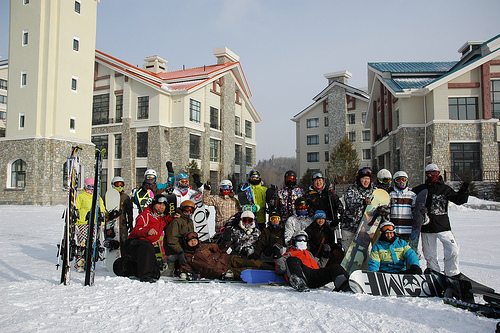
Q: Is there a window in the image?
A: Yes, there is a window.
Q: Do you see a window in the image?
A: Yes, there is a window.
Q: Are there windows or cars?
A: Yes, there is a window.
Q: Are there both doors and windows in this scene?
A: No, there is a window but no doors.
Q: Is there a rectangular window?
A: Yes, there is a rectangular window.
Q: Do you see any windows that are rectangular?
A: Yes, there is a window that is rectangular.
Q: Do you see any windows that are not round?
A: Yes, there is a rectangular window.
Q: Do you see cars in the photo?
A: No, there are no cars.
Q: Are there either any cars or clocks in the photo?
A: No, there are no cars or clocks.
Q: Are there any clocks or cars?
A: No, there are no cars or clocks.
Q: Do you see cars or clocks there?
A: No, there are no cars or clocks.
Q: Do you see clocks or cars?
A: No, there are no cars or clocks.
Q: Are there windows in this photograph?
A: Yes, there is a window.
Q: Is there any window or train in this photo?
A: Yes, there is a window.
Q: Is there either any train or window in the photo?
A: Yes, there is a window.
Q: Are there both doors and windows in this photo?
A: No, there is a window but no doors.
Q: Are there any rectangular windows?
A: Yes, there is a rectangular window.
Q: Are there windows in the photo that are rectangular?
A: Yes, there is a window that is rectangular.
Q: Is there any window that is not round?
A: Yes, there is a rectangular window.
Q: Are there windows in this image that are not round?
A: Yes, there is a rectangular window.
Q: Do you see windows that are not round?
A: Yes, there is a rectangular window.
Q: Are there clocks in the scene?
A: No, there are no clocks.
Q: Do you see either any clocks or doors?
A: No, there are no clocks or doors.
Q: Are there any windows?
A: Yes, there is a window.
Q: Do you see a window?
A: Yes, there is a window.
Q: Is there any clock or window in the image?
A: Yes, there is a window.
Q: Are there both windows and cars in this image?
A: No, there is a window but no cars.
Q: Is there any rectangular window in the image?
A: Yes, there is a rectangular window.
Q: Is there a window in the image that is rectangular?
A: Yes, there is a window that is rectangular.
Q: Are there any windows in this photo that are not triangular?
A: Yes, there is a rectangular window.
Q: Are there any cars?
A: No, there are no cars.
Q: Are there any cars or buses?
A: No, there are no cars or buses.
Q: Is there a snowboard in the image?
A: Yes, there is a snowboard.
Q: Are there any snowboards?
A: Yes, there is a snowboard.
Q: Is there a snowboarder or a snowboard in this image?
A: Yes, there is a snowboard.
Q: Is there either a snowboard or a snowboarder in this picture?
A: Yes, there is a snowboard.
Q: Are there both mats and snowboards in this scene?
A: No, there is a snowboard but no mats.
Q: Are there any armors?
A: No, there are no armors.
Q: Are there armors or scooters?
A: No, there are no armors or scooters.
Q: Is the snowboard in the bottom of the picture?
A: Yes, the snowboard is in the bottom of the image.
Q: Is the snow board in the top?
A: No, the snow board is in the bottom of the image.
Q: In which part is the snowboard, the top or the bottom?
A: The snowboard is in the bottom of the image.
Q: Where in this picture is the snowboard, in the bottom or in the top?
A: The snowboard is in the bottom of the image.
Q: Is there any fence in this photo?
A: No, there are no fences.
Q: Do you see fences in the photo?
A: No, there are no fences.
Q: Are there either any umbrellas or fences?
A: No, there are no fences or umbrellas.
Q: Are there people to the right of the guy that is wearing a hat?
A: Yes, there are people to the right of the guy.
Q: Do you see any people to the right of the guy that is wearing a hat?
A: Yes, there are people to the right of the guy.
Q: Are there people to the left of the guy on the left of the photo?
A: No, the people are to the right of the guy.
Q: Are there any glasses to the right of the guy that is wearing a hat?
A: No, there are people to the right of the guy.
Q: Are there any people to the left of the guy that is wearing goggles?
A: Yes, there are people to the left of the guy.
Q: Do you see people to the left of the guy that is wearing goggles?
A: Yes, there are people to the left of the guy.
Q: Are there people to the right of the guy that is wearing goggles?
A: No, the people are to the left of the guy.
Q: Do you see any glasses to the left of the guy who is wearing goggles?
A: No, there are people to the left of the guy.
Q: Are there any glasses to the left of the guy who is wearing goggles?
A: No, there are people to the left of the guy.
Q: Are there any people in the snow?
A: Yes, there is a person in the snow.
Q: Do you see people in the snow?
A: Yes, there is a person in the snow.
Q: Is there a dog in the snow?
A: No, there is a person in the snow.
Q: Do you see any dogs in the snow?
A: No, there is a person in the snow.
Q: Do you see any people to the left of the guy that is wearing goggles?
A: Yes, there is a person to the left of the guy.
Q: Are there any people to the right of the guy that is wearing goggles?
A: No, the person is to the left of the guy.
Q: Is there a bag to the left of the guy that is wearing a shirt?
A: No, there is a person to the left of the guy.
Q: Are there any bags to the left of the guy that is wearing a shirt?
A: No, there is a person to the left of the guy.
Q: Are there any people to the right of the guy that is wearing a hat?
A: Yes, there is a person to the right of the guy.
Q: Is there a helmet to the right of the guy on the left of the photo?
A: No, there is a person to the right of the guy.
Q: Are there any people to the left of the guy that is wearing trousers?
A: Yes, there is a person to the left of the guy.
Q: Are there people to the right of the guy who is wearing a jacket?
A: No, the person is to the left of the guy.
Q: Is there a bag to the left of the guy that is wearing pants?
A: No, there is a person to the left of the guy.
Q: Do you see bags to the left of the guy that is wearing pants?
A: No, there is a person to the left of the guy.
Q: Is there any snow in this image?
A: Yes, there is snow.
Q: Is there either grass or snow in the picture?
A: Yes, there is snow.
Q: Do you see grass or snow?
A: Yes, there is snow.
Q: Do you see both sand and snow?
A: No, there is snow but no sand.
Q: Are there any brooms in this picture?
A: No, there are no brooms.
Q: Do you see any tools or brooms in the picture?
A: No, there are no brooms or tools.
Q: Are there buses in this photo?
A: No, there are no buses.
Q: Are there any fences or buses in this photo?
A: No, there are no buses or fences.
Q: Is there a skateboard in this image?
A: No, there are no skateboards.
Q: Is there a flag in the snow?
A: No, there is a guy in the snow.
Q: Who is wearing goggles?
A: The guy is wearing goggles.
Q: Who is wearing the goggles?
A: The guy is wearing goggles.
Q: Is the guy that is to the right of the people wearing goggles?
A: Yes, the guy is wearing goggles.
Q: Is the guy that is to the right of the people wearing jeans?
A: No, the guy is wearing goggles.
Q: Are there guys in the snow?
A: Yes, there is a guy in the snow.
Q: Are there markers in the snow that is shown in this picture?
A: No, there is a guy in the snow.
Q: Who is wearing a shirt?
A: The guy is wearing a shirt.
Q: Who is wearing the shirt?
A: The guy is wearing a shirt.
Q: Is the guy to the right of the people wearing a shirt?
A: Yes, the guy is wearing a shirt.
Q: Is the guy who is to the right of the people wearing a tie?
A: No, the guy is wearing a shirt.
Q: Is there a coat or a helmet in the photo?
A: Yes, there is a coat.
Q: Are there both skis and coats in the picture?
A: Yes, there are both a coat and skis.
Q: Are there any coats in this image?
A: Yes, there is a coat.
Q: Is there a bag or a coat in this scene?
A: Yes, there is a coat.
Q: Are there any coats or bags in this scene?
A: Yes, there is a coat.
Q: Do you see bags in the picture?
A: No, there are no bags.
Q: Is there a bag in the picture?
A: No, there are no bags.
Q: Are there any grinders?
A: No, there are no grinders.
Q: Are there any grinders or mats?
A: No, there are no grinders or mats.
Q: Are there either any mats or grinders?
A: No, there are no grinders or mats.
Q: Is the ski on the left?
A: Yes, the ski is on the left of the image.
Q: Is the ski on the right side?
A: No, the ski is on the left of the image.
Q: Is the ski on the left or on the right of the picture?
A: The ski is on the left of the image.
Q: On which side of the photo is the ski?
A: The ski is on the left of the image.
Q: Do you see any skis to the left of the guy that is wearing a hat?
A: Yes, there is a ski to the left of the guy.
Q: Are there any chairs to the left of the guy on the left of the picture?
A: No, there is a ski to the left of the guy.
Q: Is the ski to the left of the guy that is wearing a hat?
A: Yes, the ski is to the left of the guy.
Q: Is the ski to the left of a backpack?
A: No, the ski is to the left of the guy.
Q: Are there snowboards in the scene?
A: Yes, there is a snowboard.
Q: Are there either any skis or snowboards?
A: Yes, there is a snowboard.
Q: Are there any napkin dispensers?
A: No, there are no napkin dispensers.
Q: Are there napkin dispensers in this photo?
A: No, there are no napkin dispensers.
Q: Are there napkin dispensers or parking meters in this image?
A: No, there are no napkin dispensers or parking meters.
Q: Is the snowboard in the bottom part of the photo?
A: Yes, the snowboard is in the bottom of the image.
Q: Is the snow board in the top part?
A: No, the snow board is in the bottom of the image.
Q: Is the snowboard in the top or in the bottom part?
A: The snowboard is in the bottom of the image.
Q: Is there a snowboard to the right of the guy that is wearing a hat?
A: Yes, there is a snowboard to the right of the guy.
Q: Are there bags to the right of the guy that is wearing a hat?
A: No, there is a snowboard to the right of the guy.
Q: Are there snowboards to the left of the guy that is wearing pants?
A: Yes, there is a snowboard to the left of the guy.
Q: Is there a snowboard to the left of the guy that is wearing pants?
A: Yes, there is a snowboard to the left of the guy.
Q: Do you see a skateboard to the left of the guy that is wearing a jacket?
A: No, there is a snowboard to the left of the guy.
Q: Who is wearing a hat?
A: The guy is wearing a hat.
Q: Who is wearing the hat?
A: The guy is wearing a hat.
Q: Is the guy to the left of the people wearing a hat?
A: Yes, the guy is wearing a hat.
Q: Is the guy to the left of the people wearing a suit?
A: No, the guy is wearing a hat.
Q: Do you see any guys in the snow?
A: Yes, there is a guy in the snow.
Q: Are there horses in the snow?
A: No, there is a guy in the snow.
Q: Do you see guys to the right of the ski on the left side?
A: Yes, there is a guy to the right of the ski.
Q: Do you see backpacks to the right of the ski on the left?
A: No, there is a guy to the right of the ski.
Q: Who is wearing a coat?
A: The guy is wearing a coat.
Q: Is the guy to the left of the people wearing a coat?
A: Yes, the guy is wearing a coat.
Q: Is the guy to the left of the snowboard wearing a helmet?
A: No, the guy is wearing a coat.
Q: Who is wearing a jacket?
A: The guy is wearing a jacket.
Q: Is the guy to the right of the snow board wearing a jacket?
A: Yes, the guy is wearing a jacket.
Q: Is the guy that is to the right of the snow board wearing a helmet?
A: No, the guy is wearing a jacket.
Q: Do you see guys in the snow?
A: Yes, there is a guy in the snow.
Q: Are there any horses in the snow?
A: No, there is a guy in the snow.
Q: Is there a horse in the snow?
A: No, there is a guy in the snow.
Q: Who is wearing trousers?
A: The guy is wearing trousers.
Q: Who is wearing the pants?
A: The guy is wearing trousers.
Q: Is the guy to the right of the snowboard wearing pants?
A: Yes, the guy is wearing pants.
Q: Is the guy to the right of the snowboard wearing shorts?
A: No, the guy is wearing pants.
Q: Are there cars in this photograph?
A: No, there are no cars.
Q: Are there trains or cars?
A: No, there are no cars or trains.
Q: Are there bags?
A: No, there are no bags.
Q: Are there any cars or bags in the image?
A: No, there are no bags or cars.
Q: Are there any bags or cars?
A: No, there are no bags or cars.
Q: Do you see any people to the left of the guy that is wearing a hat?
A: Yes, there is a person to the left of the guy.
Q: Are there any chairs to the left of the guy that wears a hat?
A: No, there is a person to the left of the guy.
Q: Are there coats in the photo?
A: Yes, there is a coat.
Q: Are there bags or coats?
A: Yes, there is a coat.